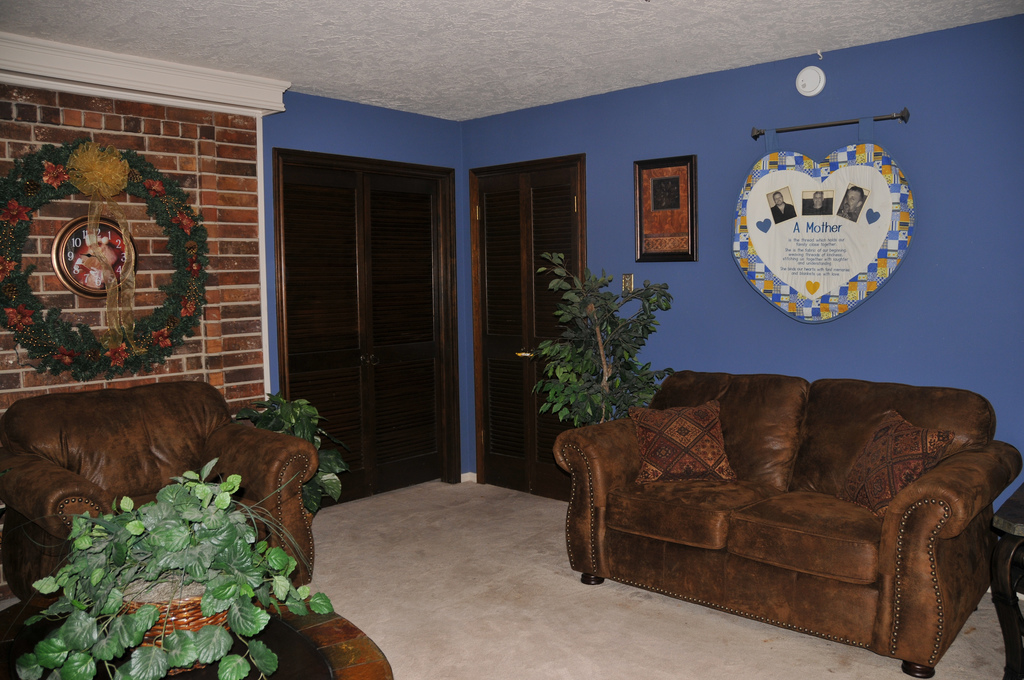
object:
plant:
[529, 247, 676, 442]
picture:
[632, 154, 697, 261]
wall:
[455, 12, 1024, 485]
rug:
[411, 552, 494, 603]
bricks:
[221, 330, 266, 355]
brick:
[216, 174, 257, 192]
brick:
[221, 240, 259, 258]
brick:
[217, 161, 258, 176]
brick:
[220, 333, 261, 351]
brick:
[141, 132, 200, 156]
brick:
[200, 234, 219, 254]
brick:
[213, 124, 259, 148]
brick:
[212, 110, 260, 132]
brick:
[95, 130, 151, 152]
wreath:
[0, 137, 212, 384]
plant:
[16, 454, 339, 679]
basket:
[96, 559, 251, 672]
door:
[469, 152, 586, 501]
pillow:
[621, 396, 741, 486]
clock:
[48, 212, 143, 301]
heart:
[725, 139, 920, 325]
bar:
[747, 104, 918, 141]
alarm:
[792, 48, 831, 99]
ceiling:
[388, 29, 554, 102]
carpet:
[377, 541, 526, 624]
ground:
[427, 474, 1024, 680]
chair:
[0, 379, 323, 585]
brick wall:
[0, 84, 272, 602]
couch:
[549, 366, 1024, 680]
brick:
[223, 362, 265, 387]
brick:
[199, 175, 216, 202]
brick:
[200, 207, 260, 239]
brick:
[149, 268, 205, 291]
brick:
[199, 317, 260, 340]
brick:
[185, 351, 221, 373]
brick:
[181, 209, 239, 254]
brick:
[201, 273, 249, 355]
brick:
[223, 364, 266, 399]